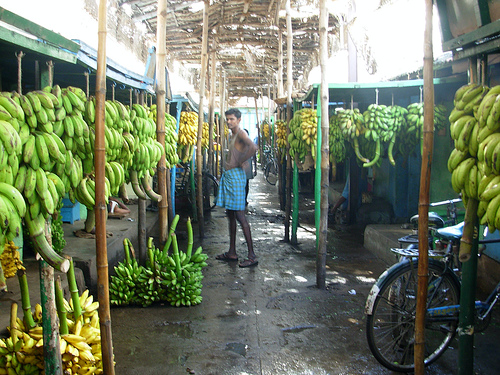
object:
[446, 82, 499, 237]
banana stalk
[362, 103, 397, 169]
banana stalk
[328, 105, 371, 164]
banana stalk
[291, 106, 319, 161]
banana stalk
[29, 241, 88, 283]
brown stem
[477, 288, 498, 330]
pedal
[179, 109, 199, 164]
banana stalk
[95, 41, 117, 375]
bamboo stick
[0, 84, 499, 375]
banana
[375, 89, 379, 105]
hook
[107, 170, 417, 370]
ground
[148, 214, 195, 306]
banana stalk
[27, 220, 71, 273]
stem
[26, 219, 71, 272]
green stem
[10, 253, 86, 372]
banana stalk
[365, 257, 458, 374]
tire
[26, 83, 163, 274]
banana stalk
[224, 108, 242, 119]
hair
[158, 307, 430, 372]
water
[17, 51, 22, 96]
hook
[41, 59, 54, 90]
hook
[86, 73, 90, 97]
hook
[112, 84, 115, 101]
hook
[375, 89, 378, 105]
hook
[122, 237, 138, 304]
banana stalk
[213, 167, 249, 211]
shorts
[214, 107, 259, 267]
man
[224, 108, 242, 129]
head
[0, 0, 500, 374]
facility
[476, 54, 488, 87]
hook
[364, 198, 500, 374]
bicycle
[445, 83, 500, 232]
bunch